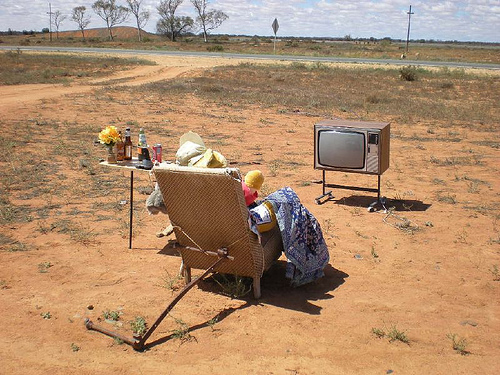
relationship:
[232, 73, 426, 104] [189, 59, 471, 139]
grass on ground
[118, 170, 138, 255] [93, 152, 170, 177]
leg on table